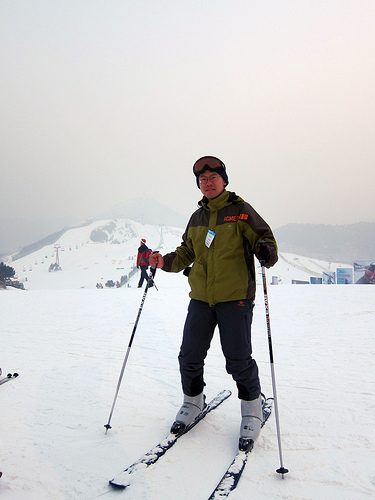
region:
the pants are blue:
[150, 277, 270, 403]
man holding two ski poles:
[103, 139, 310, 499]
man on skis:
[135, 118, 305, 472]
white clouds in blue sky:
[18, 19, 46, 59]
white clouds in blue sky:
[18, 41, 83, 110]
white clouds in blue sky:
[37, 97, 82, 148]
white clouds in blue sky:
[204, 75, 273, 100]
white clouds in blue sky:
[285, 112, 338, 184]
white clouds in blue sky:
[82, 15, 192, 114]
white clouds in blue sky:
[201, 51, 283, 149]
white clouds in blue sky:
[77, 28, 147, 103]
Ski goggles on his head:
[185, 148, 233, 178]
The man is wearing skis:
[82, 369, 297, 497]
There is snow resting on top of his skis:
[127, 430, 232, 498]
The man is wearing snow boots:
[153, 370, 272, 448]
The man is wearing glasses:
[195, 174, 226, 186]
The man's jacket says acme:
[219, 212, 240, 223]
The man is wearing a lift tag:
[196, 224, 226, 254]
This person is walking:
[124, 218, 158, 282]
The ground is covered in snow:
[18, 292, 95, 490]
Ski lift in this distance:
[17, 238, 94, 268]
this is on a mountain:
[43, 128, 332, 390]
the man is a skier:
[99, 228, 268, 406]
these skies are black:
[113, 396, 291, 491]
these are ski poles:
[97, 243, 327, 456]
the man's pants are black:
[189, 297, 267, 366]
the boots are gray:
[166, 384, 259, 446]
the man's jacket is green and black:
[166, 207, 265, 292]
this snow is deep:
[36, 276, 147, 405]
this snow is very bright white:
[19, 281, 137, 411]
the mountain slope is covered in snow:
[52, 231, 123, 302]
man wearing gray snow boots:
[169, 391, 272, 441]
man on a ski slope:
[154, 371, 309, 493]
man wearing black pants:
[174, 290, 264, 411]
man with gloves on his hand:
[253, 240, 272, 262]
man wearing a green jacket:
[188, 203, 251, 297]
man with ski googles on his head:
[189, 155, 228, 174]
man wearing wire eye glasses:
[193, 173, 219, 185]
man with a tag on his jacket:
[200, 227, 224, 250]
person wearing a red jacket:
[133, 246, 147, 269]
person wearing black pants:
[133, 261, 153, 293]